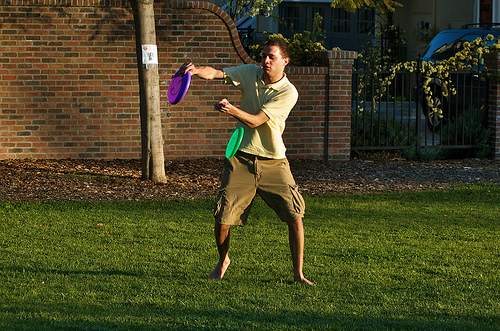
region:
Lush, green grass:
[0, 197, 499, 329]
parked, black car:
[422, 24, 497, 130]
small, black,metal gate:
[351, 56, 487, 154]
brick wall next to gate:
[0, 0, 350, 157]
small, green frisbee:
[224, 126, 243, 158]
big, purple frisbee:
[168, 68, 190, 104]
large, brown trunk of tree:
[128, 0, 185, 181]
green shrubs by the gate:
[350, 109, 487, 156]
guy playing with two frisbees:
[168, 37, 318, 285]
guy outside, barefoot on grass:
[168, 38, 338, 286]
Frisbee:
[165, 65, 196, 105]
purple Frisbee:
[161, 70, 186, 111]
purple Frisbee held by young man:
[160, 65, 186, 105]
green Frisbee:
[220, 115, 240, 170]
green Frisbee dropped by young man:
[225, 121, 245, 162]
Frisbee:
[225, 125, 240, 155]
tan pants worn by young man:
[211, 157, 301, 212]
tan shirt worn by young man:
[251, 90, 276, 145]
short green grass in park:
[16, 213, 201, 304]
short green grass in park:
[338, 204, 484, 293]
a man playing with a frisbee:
[179, 38, 324, 283]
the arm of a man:
[235, 88, 294, 126]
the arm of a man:
[192, 56, 254, 86]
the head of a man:
[259, 35, 285, 75]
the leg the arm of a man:
[212, 176, 240, 253]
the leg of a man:
[266, 159, 316, 269]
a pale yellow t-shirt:
[227, 61, 290, 149]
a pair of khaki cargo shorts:
[218, 148, 307, 228]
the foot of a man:
[210, 254, 232, 276]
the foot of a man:
[294, 274, 317, 287]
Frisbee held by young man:
[163, 61, 190, 109]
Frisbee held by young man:
[213, 120, 252, 166]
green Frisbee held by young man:
[216, 122, 244, 162]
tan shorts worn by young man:
[228, 152, 296, 209]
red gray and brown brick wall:
[18, 18, 128, 146]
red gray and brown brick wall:
[311, 77, 341, 139]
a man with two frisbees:
[151, 15, 346, 328]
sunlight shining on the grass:
[78, 225, 198, 290]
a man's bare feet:
[213, 240, 342, 301]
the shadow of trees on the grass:
[61, 266, 146, 322]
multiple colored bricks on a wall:
[11, 7, 113, 129]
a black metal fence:
[351, 57, 493, 157]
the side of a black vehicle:
[416, 20, 488, 127]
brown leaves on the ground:
[3, 159, 101, 201]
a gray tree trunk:
[132, 72, 172, 177]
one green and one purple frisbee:
[156, 62, 249, 157]